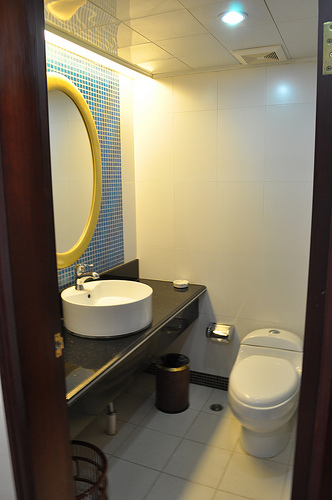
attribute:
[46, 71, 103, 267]
mirror — round, oval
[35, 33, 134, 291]
wall — tiled, blue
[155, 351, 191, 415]
trash can — wicker, small, metal, black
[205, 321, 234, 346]
dispenser — silver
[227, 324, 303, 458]
toilet — white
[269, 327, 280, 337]
button — chrome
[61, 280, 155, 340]
sink — porcelain, white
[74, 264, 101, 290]
faucet — chrome, silver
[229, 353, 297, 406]
toilet seat — white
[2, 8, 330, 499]
room — bathroom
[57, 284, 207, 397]
counter — brown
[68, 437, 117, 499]
basket — wire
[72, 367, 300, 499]
floor — white, tile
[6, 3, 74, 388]
door trim — dark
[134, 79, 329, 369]
wall — white